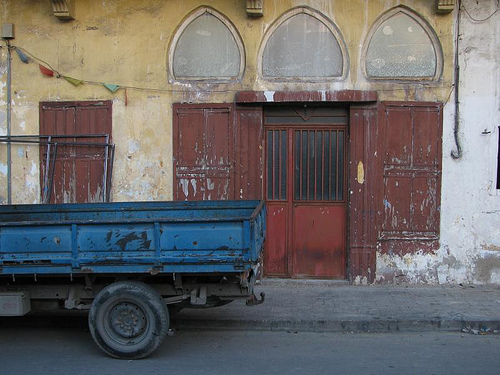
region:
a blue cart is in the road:
[3, 192, 285, 352]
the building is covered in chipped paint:
[11, 10, 484, 293]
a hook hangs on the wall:
[445, 133, 468, 173]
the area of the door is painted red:
[186, 93, 391, 286]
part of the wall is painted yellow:
[6, 12, 178, 101]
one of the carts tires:
[77, 272, 184, 363]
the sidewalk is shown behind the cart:
[263, 282, 497, 335]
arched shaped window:
[360, 5, 444, 83]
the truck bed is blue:
[0, 199, 265, 273]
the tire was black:
[85, 281, 170, 358]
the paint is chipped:
[356, 160, 363, 184]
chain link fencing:
[0, 130, 114, 202]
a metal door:
[265, 122, 343, 277]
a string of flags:
[14, 44, 122, 92]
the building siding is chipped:
[375, 251, 460, 283]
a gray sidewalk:
[175, 280, 497, 333]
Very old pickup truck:
[0, 197, 265, 357]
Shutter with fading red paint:
[370, 100, 440, 256]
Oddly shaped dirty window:
[251, 5, 346, 80]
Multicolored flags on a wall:
[10, 45, 165, 96]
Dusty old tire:
[85, 280, 165, 356]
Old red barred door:
[260, 105, 345, 275]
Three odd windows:
[165, 0, 440, 80]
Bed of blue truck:
[0, 196, 265, 273]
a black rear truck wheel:
[83, 281, 175, 363]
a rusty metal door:
[268, 111, 346, 278]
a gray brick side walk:
[294, 286, 499, 322]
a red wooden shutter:
[379, 103, 450, 256]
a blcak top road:
[217, 332, 492, 373]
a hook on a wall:
[446, 46, 466, 163]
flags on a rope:
[12, 39, 137, 89]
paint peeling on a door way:
[244, 89, 354, 101]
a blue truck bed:
[0, 203, 267, 278]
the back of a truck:
[3, 169, 282, 361]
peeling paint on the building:
[377, 184, 498, 291]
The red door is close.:
[170, 93, 440, 281]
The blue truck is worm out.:
[0, 174, 287, 359]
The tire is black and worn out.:
[87, 273, 171, 358]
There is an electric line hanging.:
[2, 26, 256, 94]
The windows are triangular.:
[162, 0, 447, 89]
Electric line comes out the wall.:
[449, 1, 463, 163]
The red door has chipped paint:
[172, 84, 441, 283]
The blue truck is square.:
[5, 202, 270, 356]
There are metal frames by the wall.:
[2, 128, 121, 215]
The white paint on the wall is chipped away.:
[372, 241, 499, 296]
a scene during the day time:
[0, 1, 499, 373]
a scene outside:
[5, 6, 499, 371]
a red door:
[243, 85, 372, 282]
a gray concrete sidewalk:
[158, 258, 498, 347]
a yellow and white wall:
[1, 4, 497, 271]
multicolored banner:
[0, 31, 245, 113]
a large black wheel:
[82, 276, 178, 361]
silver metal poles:
[0, 120, 128, 232]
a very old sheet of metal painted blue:
[71, 212, 161, 264]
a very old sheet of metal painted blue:
[0, 214, 79, 262]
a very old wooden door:
[382, 101, 442, 254]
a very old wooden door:
[171, 100, 236, 200]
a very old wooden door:
[37, 97, 111, 211]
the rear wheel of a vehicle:
[88, 283, 171, 368]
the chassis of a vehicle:
[0, 272, 252, 323]